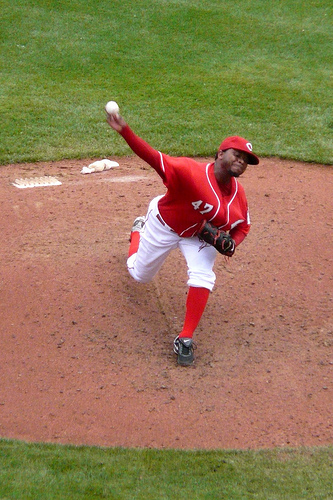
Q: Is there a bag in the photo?
A: Yes, there is a bag.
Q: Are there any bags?
A: Yes, there is a bag.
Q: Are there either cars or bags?
A: Yes, there is a bag.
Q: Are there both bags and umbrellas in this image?
A: No, there is a bag but no umbrellas.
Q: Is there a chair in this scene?
A: No, there are no chairs.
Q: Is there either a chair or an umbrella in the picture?
A: No, there are no chairs or umbrellas.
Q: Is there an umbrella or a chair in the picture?
A: No, there are no chairs or umbrellas.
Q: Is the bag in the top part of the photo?
A: Yes, the bag is in the top of the image.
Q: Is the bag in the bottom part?
A: No, the bag is in the top of the image.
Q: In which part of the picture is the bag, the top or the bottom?
A: The bag is in the top of the image.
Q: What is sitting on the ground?
A: The bag is sitting on the ground.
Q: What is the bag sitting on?
A: The bag is sitting on the ground.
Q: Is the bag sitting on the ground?
A: Yes, the bag is sitting on the ground.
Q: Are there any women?
A: No, there are no women.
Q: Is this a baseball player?
A: Yes, this is a baseball player.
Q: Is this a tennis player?
A: No, this is a baseball player.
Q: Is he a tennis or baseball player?
A: This is a baseball player.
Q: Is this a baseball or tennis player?
A: This is a baseball player.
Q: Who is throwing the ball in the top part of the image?
A: The player is throwing the ball.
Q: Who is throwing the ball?
A: The player is throwing the ball.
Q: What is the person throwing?
A: The player is throwing the ball.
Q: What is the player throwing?
A: The player is throwing the ball.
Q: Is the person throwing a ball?
A: Yes, the player is throwing a ball.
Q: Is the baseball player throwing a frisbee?
A: No, the player is throwing a ball.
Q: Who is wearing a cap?
A: The player is wearing a cap.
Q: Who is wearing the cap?
A: The player is wearing a cap.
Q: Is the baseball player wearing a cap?
A: Yes, the player is wearing a cap.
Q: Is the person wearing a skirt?
A: No, the player is wearing a cap.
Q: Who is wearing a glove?
A: The player is wearing a glove.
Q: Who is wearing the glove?
A: The player is wearing a glove.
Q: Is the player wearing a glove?
A: Yes, the player is wearing a glove.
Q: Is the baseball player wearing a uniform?
A: No, the player is wearing a glove.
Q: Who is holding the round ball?
A: The player is holding the ball.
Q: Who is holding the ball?
A: The player is holding the ball.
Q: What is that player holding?
A: The player is holding the ball.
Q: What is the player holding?
A: The player is holding the ball.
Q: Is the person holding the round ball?
A: Yes, the player is holding the ball.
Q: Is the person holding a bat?
A: No, the player is holding the ball.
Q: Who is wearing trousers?
A: The player is wearing trousers.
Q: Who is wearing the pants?
A: The player is wearing trousers.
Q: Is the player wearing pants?
A: Yes, the player is wearing pants.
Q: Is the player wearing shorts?
A: No, the player is wearing pants.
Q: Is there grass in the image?
A: Yes, there is grass.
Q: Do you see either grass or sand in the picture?
A: Yes, there is grass.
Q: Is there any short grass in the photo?
A: Yes, there is short grass.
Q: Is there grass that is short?
A: Yes, there is grass that is short.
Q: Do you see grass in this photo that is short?
A: Yes, there is grass that is short.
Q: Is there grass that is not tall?
A: Yes, there is short grass.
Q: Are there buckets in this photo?
A: No, there are no buckets.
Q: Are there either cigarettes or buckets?
A: No, there are no buckets or cigarettes.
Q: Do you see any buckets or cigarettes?
A: No, there are no buckets or cigarettes.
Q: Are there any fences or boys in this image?
A: No, there are no fences or boys.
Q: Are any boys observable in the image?
A: No, there are no boys.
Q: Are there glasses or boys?
A: No, there are no boys or glasses.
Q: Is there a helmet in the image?
A: No, there are no helmets.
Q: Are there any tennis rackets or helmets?
A: No, there are no helmets or tennis rackets.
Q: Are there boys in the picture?
A: No, there are no boys.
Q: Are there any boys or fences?
A: No, there are no boys or fences.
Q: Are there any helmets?
A: No, there are no helmets.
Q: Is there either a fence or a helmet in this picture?
A: No, there are no helmets or fences.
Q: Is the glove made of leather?
A: Yes, the glove is made of leather.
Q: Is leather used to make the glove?
A: Yes, the glove is made of leather.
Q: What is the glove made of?
A: The glove is made of leather.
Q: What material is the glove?
A: The glove is made of leather.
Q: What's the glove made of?
A: The glove is made of leather.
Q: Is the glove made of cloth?
A: No, the glove is made of leather.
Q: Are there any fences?
A: No, there are no fences.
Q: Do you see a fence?
A: No, there are no fences.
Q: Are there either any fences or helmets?
A: No, there are no fences or helmets.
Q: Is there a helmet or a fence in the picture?
A: No, there are no fences or helmets.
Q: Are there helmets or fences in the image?
A: No, there are no fences or helmets.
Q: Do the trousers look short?
A: Yes, the trousers are short.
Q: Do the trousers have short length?
A: Yes, the trousers are short.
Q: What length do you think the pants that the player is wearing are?
A: The pants are short.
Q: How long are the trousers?
A: The trousers are short.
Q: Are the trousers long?
A: No, the trousers are short.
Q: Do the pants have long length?
A: No, the pants are short.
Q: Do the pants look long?
A: No, the pants are short.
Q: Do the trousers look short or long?
A: The trousers are short.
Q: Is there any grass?
A: Yes, there is grass.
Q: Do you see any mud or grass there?
A: Yes, there is grass.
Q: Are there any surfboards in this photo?
A: No, there are no surfboards.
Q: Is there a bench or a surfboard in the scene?
A: No, there are no surfboards or benches.